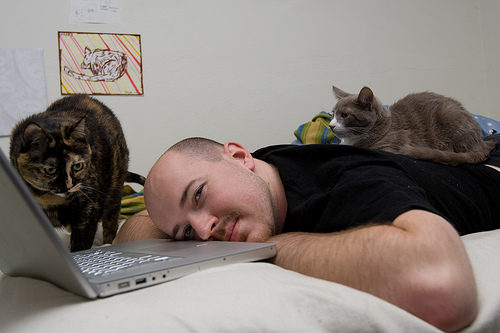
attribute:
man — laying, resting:
[110, 138, 500, 332]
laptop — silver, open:
[0, 144, 277, 299]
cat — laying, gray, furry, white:
[329, 85, 497, 165]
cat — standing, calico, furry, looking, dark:
[10, 95, 130, 253]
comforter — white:
[0, 217, 499, 331]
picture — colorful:
[57, 31, 145, 97]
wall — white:
[0, 1, 499, 193]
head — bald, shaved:
[142, 138, 286, 243]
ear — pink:
[225, 141, 255, 172]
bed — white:
[0, 219, 499, 333]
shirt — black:
[250, 144, 500, 237]